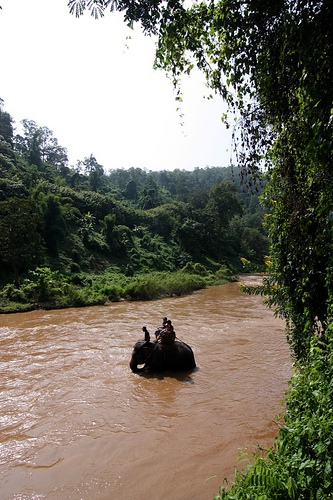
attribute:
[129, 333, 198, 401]
elephant — carrying people